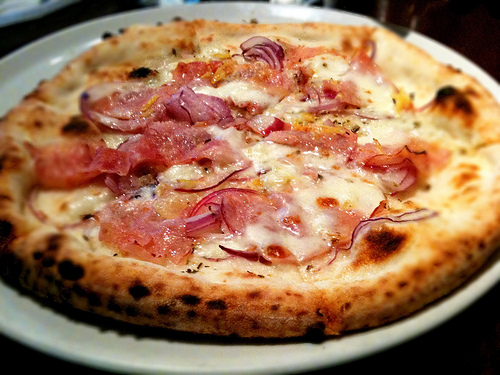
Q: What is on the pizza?
A: Melted cheese.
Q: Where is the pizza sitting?
A: On the plate.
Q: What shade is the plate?
A: White.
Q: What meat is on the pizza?
A: Ham.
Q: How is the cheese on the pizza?
A: Melted.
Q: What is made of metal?
A: Tray.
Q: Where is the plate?
A: On the table.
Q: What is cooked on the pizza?
A: Meat.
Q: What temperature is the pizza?
A: Hot.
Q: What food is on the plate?
A: Pizza.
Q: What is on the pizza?
A: Onions.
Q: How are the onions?
A: Sliced.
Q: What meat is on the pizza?
A: Bacon.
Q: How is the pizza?
A: Sliced.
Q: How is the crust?
A: Toasted.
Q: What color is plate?
A: White.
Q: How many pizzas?
A: One.